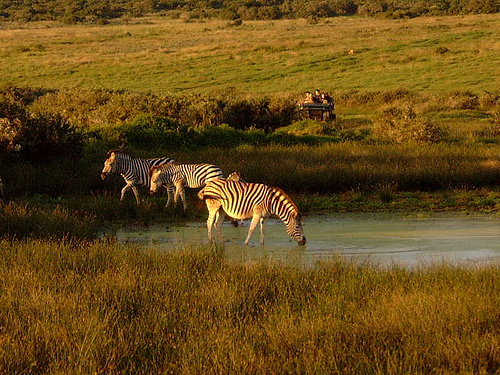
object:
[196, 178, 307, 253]
zebra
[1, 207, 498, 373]
pasture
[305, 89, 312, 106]
people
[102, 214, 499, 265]
water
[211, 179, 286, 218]
stripes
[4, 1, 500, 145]
field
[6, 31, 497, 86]
grass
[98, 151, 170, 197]
zebra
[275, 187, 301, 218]
hair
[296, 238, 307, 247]
nose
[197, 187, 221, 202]
tail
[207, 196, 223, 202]
hair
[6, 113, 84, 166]
bushes